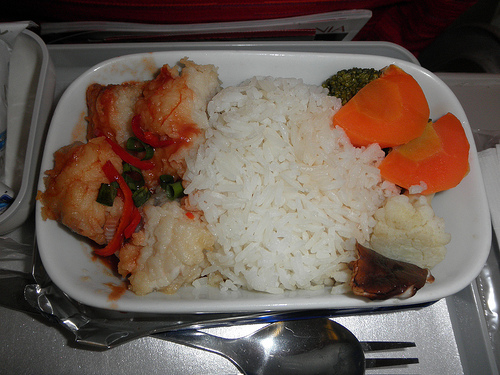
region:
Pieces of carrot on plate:
[344, 64, 471, 191]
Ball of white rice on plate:
[202, 76, 370, 297]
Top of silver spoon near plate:
[245, 313, 380, 374]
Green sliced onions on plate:
[102, 169, 186, 206]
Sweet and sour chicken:
[43, 46, 218, 239]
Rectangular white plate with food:
[32, 51, 488, 303]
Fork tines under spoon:
[364, 338, 414, 374]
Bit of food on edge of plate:
[347, 239, 430, 300]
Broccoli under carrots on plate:
[321, 61, 386, 94]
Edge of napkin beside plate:
[475, 135, 498, 252]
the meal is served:
[35, 40, 491, 310]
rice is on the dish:
[195, 76, 370, 291]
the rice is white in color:
[200, 80, 385, 290]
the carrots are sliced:
[340, 65, 465, 195]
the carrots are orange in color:
[325, 60, 470, 196]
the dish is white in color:
[37, 48, 488, 319]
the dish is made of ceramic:
[34, 49, 491, 316]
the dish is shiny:
[42, 50, 492, 312]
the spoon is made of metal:
[3, 277, 367, 374]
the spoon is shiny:
[4, 268, 365, 372]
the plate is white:
[22, 52, 481, 348]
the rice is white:
[195, 85, 333, 258]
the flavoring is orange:
[70, 77, 161, 225]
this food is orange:
[341, 70, 467, 190]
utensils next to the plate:
[59, 299, 416, 374]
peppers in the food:
[75, 124, 176, 259]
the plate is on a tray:
[0, 30, 489, 362]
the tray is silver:
[404, 273, 499, 372]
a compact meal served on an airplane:
[26, 45, 495, 321]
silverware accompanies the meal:
[12, 286, 442, 371]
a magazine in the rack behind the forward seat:
[31, 5, 378, 41]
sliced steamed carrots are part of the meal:
[331, 65, 468, 194]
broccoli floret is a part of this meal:
[319, 66, 388, 106]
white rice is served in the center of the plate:
[193, 70, 377, 290]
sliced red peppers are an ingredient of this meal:
[96, 133, 146, 265]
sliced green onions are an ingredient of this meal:
[95, 134, 182, 208]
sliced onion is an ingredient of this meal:
[100, 210, 124, 252]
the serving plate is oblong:
[30, 40, 497, 318]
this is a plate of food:
[20, 23, 499, 333]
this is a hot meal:
[39, 40, 489, 329]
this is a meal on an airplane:
[31, 26, 498, 323]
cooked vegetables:
[336, 51, 481, 206]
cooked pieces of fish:
[69, 55, 248, 316]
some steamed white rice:
[180, 42, 420, 302]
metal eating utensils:
[48, 305, 478, 373]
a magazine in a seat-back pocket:
[33, 10, 409, 60]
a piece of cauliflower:
[365, 188, 485, 263]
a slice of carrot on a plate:
[339, 67, 429, 154]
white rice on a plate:
[222, 75, 345, 295]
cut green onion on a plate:
[152, 167, 182, 205]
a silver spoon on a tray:
[232, 316, 369, 373]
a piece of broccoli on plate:
[325, 56, 384, 102]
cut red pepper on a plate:
[106, 149, 134, 271]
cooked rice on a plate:
[221, 71, 359, 303]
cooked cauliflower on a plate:
[381, 179, 441, 275]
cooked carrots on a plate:
[343, 65, 468, 204]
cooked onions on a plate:
[122, 136, 183, 206]